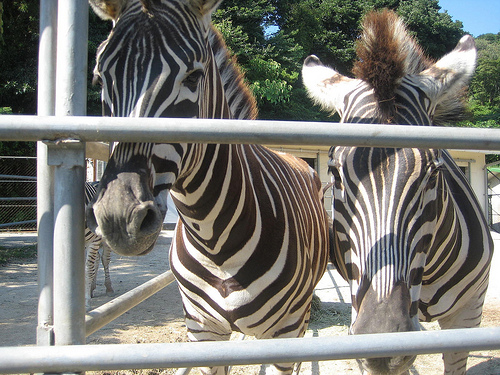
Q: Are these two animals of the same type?
A: Yes, all the animals are zebras.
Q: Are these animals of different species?
A: No, all the animals are zebras.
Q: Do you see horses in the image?
A: No, there are no horses.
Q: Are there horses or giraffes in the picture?
A: No, there are no horses or giraffes.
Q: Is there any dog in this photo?
A: No, there are no dogs.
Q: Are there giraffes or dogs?
A: No, there are no dogs or giraffes.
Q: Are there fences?
A: Yes, there is a fence.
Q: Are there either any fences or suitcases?
A: Yes, there is a fence.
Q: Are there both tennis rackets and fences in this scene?
A: No, there is a fence but no rackets.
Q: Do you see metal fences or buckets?
A: Yes, there is a metal fence.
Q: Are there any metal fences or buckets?
A: Yes, there is a metal fence.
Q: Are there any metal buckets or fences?
A: Yes, there is a metal fence.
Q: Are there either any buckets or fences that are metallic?
A: Yes, the fence is metallic.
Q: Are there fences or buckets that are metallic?
A: Yes, the fence is metallic.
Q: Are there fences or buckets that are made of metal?
A: Yes, the fence is made of metal.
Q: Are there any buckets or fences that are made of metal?
A: Yes, the fence is made of metal.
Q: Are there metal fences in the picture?
A: Yes, there is a metal fence.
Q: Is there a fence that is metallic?
A: Yes, there is a fence that is metallic.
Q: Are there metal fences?
A: Yes, there is a fence that is made of metal.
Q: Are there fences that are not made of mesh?
A: Yes, there is a fence that is made of metal.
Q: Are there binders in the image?
A: No, there are no binders.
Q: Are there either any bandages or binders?
A: No, there are no binders or bandages.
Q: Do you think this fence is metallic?
A: Yes, the fence is metallic.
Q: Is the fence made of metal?
A: Yes, the fence is made of metal.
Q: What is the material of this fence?
A: The fence is made of metal.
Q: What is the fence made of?
A: The fence is made of metal.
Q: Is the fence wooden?
A: No, the fence is metallic.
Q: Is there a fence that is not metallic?
A: No, there is a fence but it is metallic.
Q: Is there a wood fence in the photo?
A: No, there is a fence but it is made of metal.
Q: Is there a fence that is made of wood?
A: No, there is a fence but it is made of metal.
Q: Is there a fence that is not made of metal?
A: No, there is a fence but it is made of metal.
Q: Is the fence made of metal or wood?
A: The fence is made of metal.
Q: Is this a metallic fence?
A: Yes, this is a metallic fence.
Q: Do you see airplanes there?
A: No, there are no airplanes.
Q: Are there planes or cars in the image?
A: No, there are no planes or cars.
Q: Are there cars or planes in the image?
A: No, there are no planes or cars.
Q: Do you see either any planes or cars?
A: No, there are no planes or cars.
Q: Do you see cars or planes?
A: No, there are no planes or cars.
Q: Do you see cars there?
A: No, there are no cars.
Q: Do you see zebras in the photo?
A: Yes, there is a zebra.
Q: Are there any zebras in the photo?
A: Yes, there is a zebra.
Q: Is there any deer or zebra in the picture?
A: Yes, there is a zebra.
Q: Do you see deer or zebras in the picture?
A: Yes, there is a zebra.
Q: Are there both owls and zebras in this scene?
A: No, there is a zebra but no owls.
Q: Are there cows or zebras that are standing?
A: Yes, the zebra is standing.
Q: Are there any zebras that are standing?
A: Yes, there is a zebra that is standing.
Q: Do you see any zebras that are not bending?
A: Yes, there is a zebra that is standing .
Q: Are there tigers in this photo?
A: No, there are no tigers.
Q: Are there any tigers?
A: No, there are no tigers.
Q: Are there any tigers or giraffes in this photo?
A: No, there are no tigers or giraffes.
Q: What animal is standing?
A: The animal is a zebra.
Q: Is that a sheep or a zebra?
A: That is a zebra.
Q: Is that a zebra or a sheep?
A: That is a zebra.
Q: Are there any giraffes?
A: No, there are no giraffes.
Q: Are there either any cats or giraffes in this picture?
A: No, there are no giraffes or cats.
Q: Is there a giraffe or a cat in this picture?
A: No, there are no giraffes or cats.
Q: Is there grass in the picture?
A: Yes, there is grass.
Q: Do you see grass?
A: Yes, there is grass.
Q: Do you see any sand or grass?
A: Yes, there is grass.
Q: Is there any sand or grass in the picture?
A: Yes, there is grass.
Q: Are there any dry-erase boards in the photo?
A: No, there are no dry-erase boards.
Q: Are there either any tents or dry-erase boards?
A: No, there are no dry-erase boards or tents.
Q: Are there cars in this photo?
A: No, there are no cars.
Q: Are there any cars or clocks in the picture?
A: No, there are no cars or clocks.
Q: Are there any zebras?
A: Yes, there is a zebra.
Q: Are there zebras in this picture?
A: Yes, there is a zebra.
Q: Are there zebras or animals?
A: Yes, there is a zebra.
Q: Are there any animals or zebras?
A: Yes, there is a zebra.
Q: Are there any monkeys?
A: No, there are no monkeys.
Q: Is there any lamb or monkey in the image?
A: No, there are no monkeys or lambs.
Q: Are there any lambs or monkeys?
A: No, there are no monkeys or lambs.